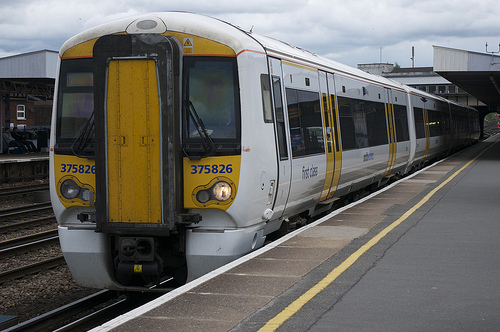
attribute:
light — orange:
[164, 164, 252, 211]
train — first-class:
[385, 88, 397, 170]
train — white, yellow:
[155, 30, 390, 170]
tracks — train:
[3, 175, 82, 331]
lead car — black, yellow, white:
[40, 12, 301, 284]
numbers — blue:
[190, 162, 241, 175]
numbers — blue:
[60, 155, 97, 179]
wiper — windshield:
[182, 102, 213, 156]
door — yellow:
[106, 62, 161, 227]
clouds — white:
[231, 4, 498, 64]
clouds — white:
[0, 3, 498, 66]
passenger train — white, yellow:
[48, 9, 485, 293]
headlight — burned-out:
[50, 172, 108, 229]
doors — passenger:
[318, 71, 340, 203]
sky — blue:
[257, 1, 484, 49]